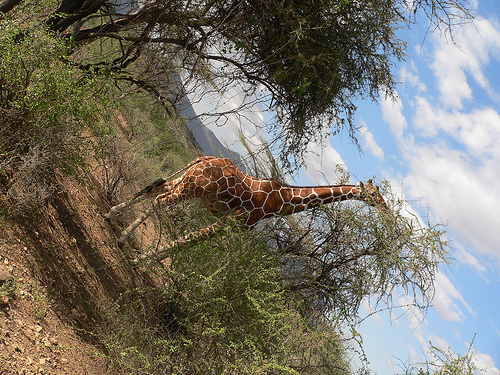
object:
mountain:
[188, 126, 240, 155]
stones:
[24, 246, 28, 251]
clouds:
[439, 137, 498, 190]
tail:
[131, 155, 217, 201]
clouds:
[357, 117, 386, 163]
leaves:
[355, 249, 389, 278]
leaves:
[375, 242, 402, 266]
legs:
[115, 183, 185, 249]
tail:
[132, 156, 221, 202]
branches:
[310, 223, 342, 254]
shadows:
[10, 185, 133, 357]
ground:
[11, 214, 100, 367]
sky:
[378, 17, 500, 336]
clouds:
[429, 0, 498, 54]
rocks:
[4, 318, 60, 349]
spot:
[217, 191, 236, 203]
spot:
[279, 187, 293, 203]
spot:
[217, 176, 229, 192]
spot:
[313, 188, 332, 200]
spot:
[262, 190, 283, 214]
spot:
[341, 186, 353, 195]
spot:
[196, 176, 211, 187]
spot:
[184, 183, 190, 189]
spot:
[246, 208, 266, 226]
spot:
[216, 209, 230, 220]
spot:
[309, 193, 317, 199]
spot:
[292, 188, 301, 196]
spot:
[250, 191, 268, 209]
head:
[359, 178, 389, 214]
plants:
[131, 197, 298, 375]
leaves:
[220, 302, 251, 339]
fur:
[294, 187, 322, 205]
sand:
[0, 214, 46, 303]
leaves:
[354, 206, 385, 240]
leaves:
[275, 299, 289, 331]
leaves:
[328, 236, 352, 258]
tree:
[35, 57, 403, 176]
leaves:
[353, 223, 372, 242]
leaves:
[443, 357, 464, 366]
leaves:
[416, 255, 429, 265]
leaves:
[320, 206, 357, 231]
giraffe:
[103, 155, 392, 272]